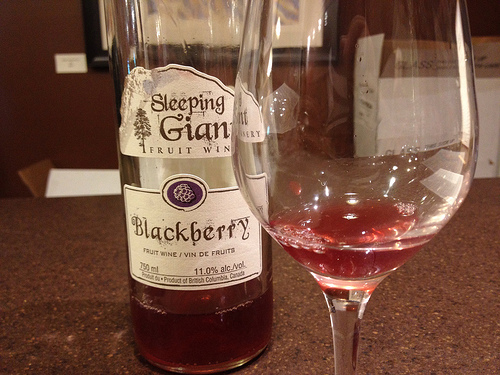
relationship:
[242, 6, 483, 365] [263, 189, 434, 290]
glass of wine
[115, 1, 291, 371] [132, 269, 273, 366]
bottle of wine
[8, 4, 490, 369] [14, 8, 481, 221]
scene  inside